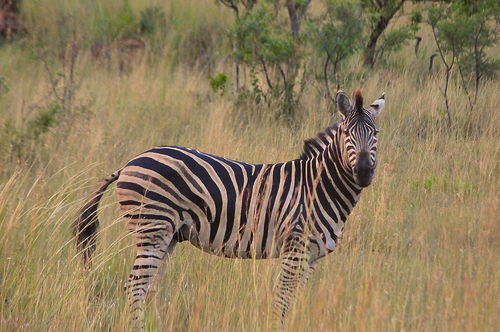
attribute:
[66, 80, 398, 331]
zebra — striped, black, white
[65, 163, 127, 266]
tail — black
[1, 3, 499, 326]
plain — daytime, outdoors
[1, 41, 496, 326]
grass — long, brown, green, long brown, dried out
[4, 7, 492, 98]
bushes — wild green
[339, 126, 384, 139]
two eyes — black